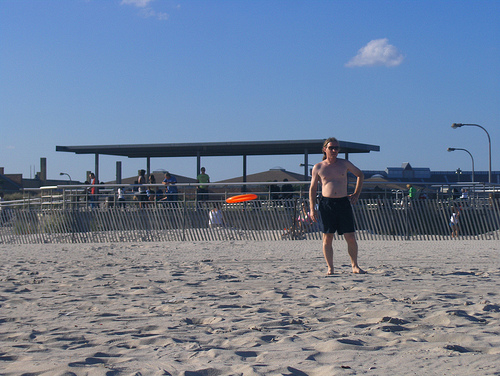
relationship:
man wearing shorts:
[308, 136, 368, 274] [292, 174, 367, 252]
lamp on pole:
[451, 116, 461, 131] [427, 108, 498, 226]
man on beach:
[308, 136, 368, 274] [105, 262, 347, 324]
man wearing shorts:
[308, 136, 368, 274] [318, 193, 357, 235]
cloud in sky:
[341, 45, 405, 80] [12, 5, 486, 162]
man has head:
[308, 136, 368, 274] [320, 135, 339, 160]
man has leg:
[308, 136, 368, 274] [319, 230, 337, 277]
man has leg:
[308, 136, 368, 274] [342, 230, 369, 276]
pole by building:
[58, 170, 70, 182] [28, 180, 78, 184]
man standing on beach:
[299, 127, 388, 277] [6, 227, 482, 371]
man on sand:
[308, 136, 368, 274] [2, 241, 498, 371]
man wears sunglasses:
[308, 136, 368, 274] [326, 141, 338, 150]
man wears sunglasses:
[308, 136, 368, 274] [325, 141, 342, 151]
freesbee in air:
[217, 185, 264, 205] [2, 6, 492, 196]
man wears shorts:
[308, 136, 368, 274] [315, 193, 358, 235]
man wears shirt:
[162, 172, 178, 200] [162, 177, 177, 190]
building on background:
[337, 163, 499, 225] [5, 161, 495, 207]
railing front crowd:
[18, 181, 311, 207] [85, 167, 470, 239]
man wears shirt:
[194, 163, 209, 200] [198, 176, 208, 187]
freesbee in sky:
[225, 193, 257, 202] [1, 1, 498, 180]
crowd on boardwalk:
[35, 158, 470, 218] [80, 175, 303, 202]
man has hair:
[308, 136, 368, 274] [317, 132, 339, 157]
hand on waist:
[345, 185, 357, 198] [315, 189, 355, 204]